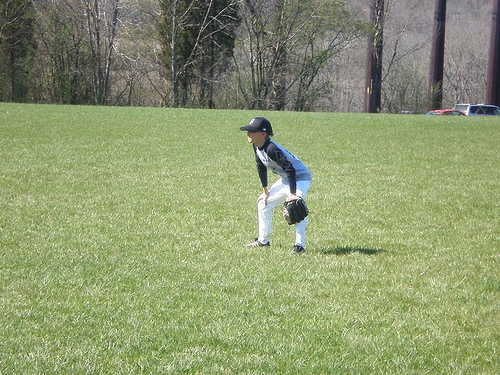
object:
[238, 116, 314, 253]
boy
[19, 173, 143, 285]
area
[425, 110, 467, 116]
car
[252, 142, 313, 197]
shirt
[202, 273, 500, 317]
grass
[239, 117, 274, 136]
cap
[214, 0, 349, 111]
tree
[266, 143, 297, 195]
sleeve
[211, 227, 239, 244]
pant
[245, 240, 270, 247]
shoe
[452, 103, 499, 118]
van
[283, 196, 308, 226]
glove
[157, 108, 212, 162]
field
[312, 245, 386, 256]
shadow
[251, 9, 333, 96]
no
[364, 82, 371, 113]
pole